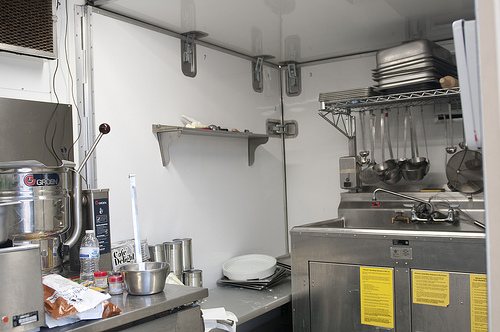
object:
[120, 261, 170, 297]
mixing bowl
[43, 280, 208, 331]
counter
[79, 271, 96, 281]
water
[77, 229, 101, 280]
bottle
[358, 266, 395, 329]
signs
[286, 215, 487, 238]
sink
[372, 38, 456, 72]
pans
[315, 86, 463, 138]
shelf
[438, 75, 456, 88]
rolling pin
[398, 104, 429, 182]
ladles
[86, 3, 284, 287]
wall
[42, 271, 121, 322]
bags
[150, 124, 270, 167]
shelf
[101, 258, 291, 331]
counter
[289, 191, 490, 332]
equipment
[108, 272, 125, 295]
spice bottle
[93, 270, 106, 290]
spice bottle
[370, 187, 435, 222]
faucet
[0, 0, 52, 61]
exhaust vent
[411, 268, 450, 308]
sign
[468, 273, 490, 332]
sign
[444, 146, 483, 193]
strainer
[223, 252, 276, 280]
cake pan